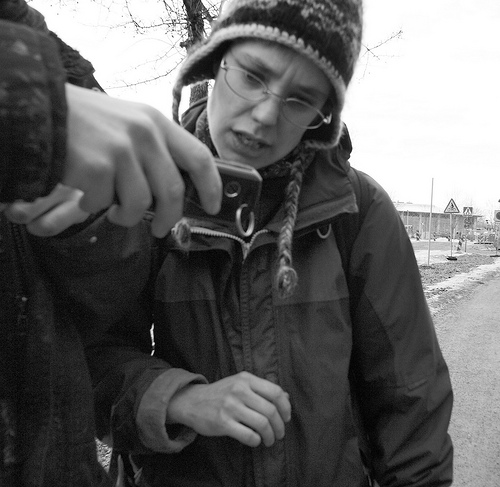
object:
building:
[404, 189, 486, 242]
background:
[407, 141, 468, 185]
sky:
[405, 22, 498, 126]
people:
[3, 2, 473, 483]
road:
[454, 296, 495, 364]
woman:
[165, 3, 379, 183]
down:
[211, 47, 353, 134]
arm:
[113, 335, 303, 466]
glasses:
[217, 57, 330, 134]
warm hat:
[189, 3, 374, 59]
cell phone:
[223, 157, 264, 241]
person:
[164, 5, 367, 116]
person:
[2, 4, 131, 464]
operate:
[237, 177, 252, 196]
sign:
[439, 194, 461, 217]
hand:
[189, 362, 299, 457]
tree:
[81, 0, 192, 78]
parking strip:
[434, 277, 477, 298]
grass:
[445, 262, 459, 275]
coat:
[186, 219, 492, 463]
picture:
[6, 5, 484, 478]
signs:
[441, 194, 479, 221]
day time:
[407, 53, 447, 86]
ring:
[234, 199, 259, 238]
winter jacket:
[273, 188, 450, 470]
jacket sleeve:
[103, 343, 214, 458]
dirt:
[445, 290, 464, 298]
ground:
[470, 305, 495, 350]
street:
[461, 312, 488, 345]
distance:
[457, 126, 470, 139]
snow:
[455, 277, 464, 286]